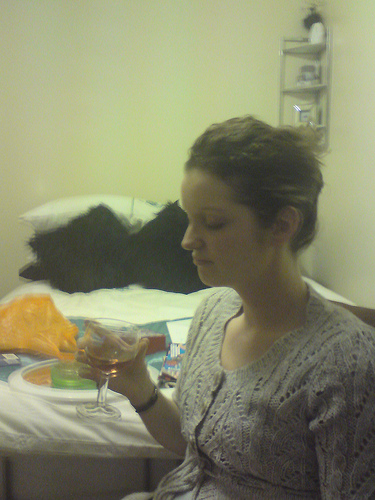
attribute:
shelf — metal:
[259, 39, 372, 167]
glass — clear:
[94, 264, 142, 410]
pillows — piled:
[54, 193, 180, 310]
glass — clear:
[86, 337, 135, 390]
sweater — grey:
[168, 264, 334, 472]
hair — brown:
[182, 67, 321, 238]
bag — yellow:
[10, 290, 91, 437]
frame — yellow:
[285, 87, 333, 154]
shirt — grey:
[152, 301, 363, 459]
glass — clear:
[75, 302, 132, 383]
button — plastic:
[198, 390, 213, 392]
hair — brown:
[165, 132, 370, 225]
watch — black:
[121, 383, 178, 418]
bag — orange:
[10, 282, 62, 334]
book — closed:
[152, 345, 216, 387]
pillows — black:
[27, 209, 258, 326]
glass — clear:
[66, 317, 134, 408]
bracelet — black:
[133, 373, 161, 425]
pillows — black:
[17, 159, 235, 294]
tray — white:
[9, 337, 148, 448]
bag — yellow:
[5, 258, 74, 397]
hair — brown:
[151, 82, 309, 208]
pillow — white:
[26, 195, 160, 232]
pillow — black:
[30, 201, 132, 294]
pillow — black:
[122, 201, 207, 293]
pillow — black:
[20, 262, 50, 276]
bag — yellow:
[2, 293, 79, 362]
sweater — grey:
[151, 285, 373, 497]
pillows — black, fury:
[20, 205, 200, 295]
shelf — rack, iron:
[277, 36, 328, 151]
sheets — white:
[1, 272, 198, 456]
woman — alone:
[75, 115, 373, 498]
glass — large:
[69, 315, 146, 425]